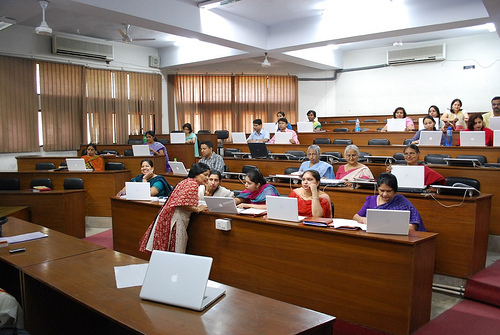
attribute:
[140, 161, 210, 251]
teacher — female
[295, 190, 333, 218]
shirt — red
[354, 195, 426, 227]
shirt — purple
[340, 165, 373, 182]
shirt — pink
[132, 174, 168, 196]
shirt — blue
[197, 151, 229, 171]
shirt — striped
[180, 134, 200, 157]
shirt — green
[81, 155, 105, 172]
shirt — orange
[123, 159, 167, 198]
woman — smiling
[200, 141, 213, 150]
hair — black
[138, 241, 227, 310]
laptop — white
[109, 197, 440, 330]
desk — wood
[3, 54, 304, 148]
shades — brown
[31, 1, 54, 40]
light — white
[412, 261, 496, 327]
rug — red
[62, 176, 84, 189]
chair — black